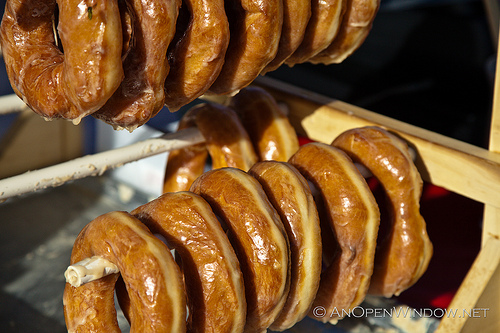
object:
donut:
[173, 166, 297, 331]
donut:
[280, 140, 381, 324]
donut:
[246, 160, 320, 331]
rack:
[0, 2, 497, 330]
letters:
[312, 303, 489, 320]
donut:
[91, 0, 181, 133]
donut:
[127, 191, 248, 331]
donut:
[164, 104, 258, 194]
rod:
[2, 102, 291, 207]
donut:
[226, 91, 300, 164]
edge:
[362, 162, 386, 187]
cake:
[332, 125, 435, 298]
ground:
[460, 77, 489, 106]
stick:
[0, 125, 205, 201]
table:
[2, 175, 144, 329]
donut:
[63, 211, 188, 331]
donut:
[1, 0, 124, 126]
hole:
[97, 261, 134, 329]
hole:
[34, 7, 63, 66]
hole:
[197, 147, 212, 182]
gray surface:
[0, 169, 410, 329]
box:
[255, 77, 499, 332]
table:
[247, 72, 499, 331]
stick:
[67, 256, 102, 284]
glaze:
[69, 108, 97, 127]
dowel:
[3, 125, 203, 201]